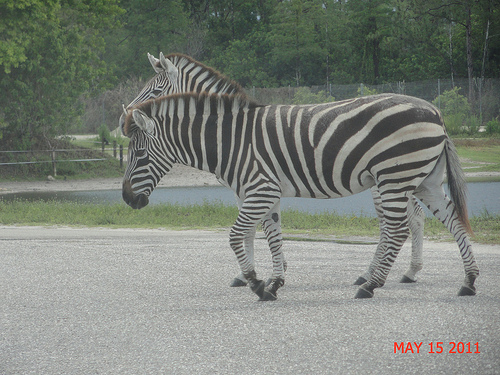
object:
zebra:
[121, 92, 481, 302]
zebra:
[118, 48, 426, 289]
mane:
[122, 91, 257, 139]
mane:
[154, 52, 248, 97]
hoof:
[251, 279, 265, 299]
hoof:
[352, 287, 373, 299]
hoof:
[456, 285, 476, 296]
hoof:
[229, 277, 246, 287]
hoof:
[257, 289, 279, 301]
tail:
[440, 112, 478, 243]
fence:
[245, 79, 500, 146]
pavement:
[1, 222, 500, 375]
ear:
[158, 50, 178, 75]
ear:
[146, 51, 161, 74]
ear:
[132, 108, 155, 134]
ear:
[122, 103, 130, 116]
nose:
[121, 182, 137, 207]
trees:
[466, 1, 500, 126]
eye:
[134, 148, 147, 157]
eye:
[149, 88, 164, 97]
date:
[392, 339, 482, 355]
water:
[0, 179, 500, 220]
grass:
[0, 196, 500, 245]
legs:
[227, 176, 284, 300]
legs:
[352, 168, 422, 300]